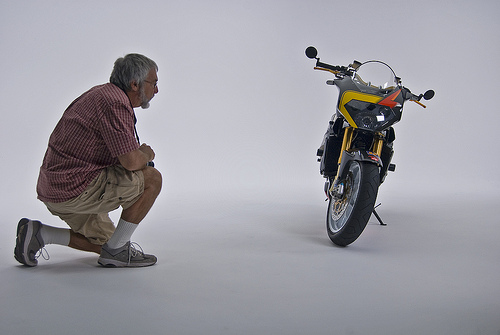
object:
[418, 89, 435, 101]
mirror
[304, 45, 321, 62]
mirror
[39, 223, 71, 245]
sock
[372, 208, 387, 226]
kickstand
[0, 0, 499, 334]
white room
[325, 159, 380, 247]
wheel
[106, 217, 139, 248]
sock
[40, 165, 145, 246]
man's shorts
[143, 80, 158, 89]
glasses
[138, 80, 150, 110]
beard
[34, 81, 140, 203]
checkered shirt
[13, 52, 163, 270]
man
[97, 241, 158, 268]
shoe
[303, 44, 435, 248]
bike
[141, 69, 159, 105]
face